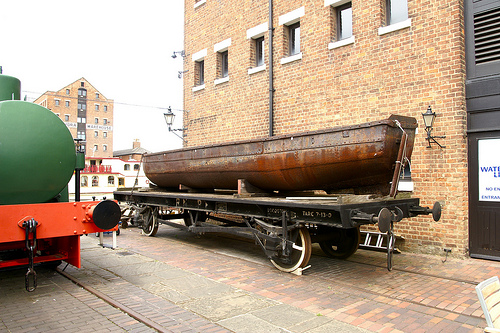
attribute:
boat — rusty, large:
[143, 115, 419, 192]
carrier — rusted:
[109, 185, 445, 275]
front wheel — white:
[261, 219, 314, 271]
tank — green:
[2, 65, 91, 207]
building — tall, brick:
[183, 1, 469, 257]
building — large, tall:
[30, 77, 114, 156]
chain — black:
[21, 217, 40, 292]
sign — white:
[475, 135, 499, 205]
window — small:
[282, 17, 302, 60]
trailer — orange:
[0, 198, 121, 291]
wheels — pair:
[266, 215, 365, 272]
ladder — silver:
[360, 227, 406, 255]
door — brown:
[466, 127, 500, 259]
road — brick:
[0, 234, 499, 333]